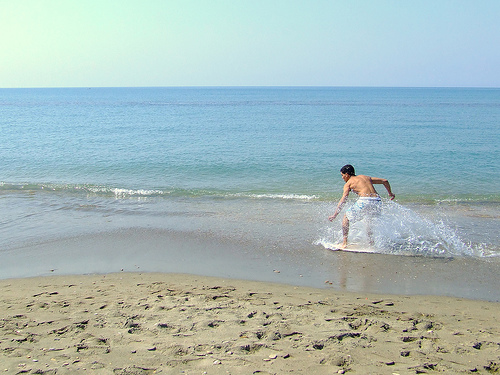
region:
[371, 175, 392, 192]
right arm of young man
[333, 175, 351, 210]
Left arm of young man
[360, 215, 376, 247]
right leg of young man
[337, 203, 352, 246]
Left leg of young man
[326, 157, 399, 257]
Young man of surfboard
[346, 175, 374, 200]
Young man's strong back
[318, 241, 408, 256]
White surfboard in water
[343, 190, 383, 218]
Young man's white swim shorts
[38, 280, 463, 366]
Footprints in the sand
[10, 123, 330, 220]
Blue ocean with small waves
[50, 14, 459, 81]
The sky is blue.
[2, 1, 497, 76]
There are no clouds in the sky.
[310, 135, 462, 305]
There is one boogie boarder.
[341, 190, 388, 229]
His shorts are white.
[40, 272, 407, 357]
Footprints in the sand.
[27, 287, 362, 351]
The sand is tan.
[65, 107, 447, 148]
The ocean is blue.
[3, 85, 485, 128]
No one swimming in the ocean.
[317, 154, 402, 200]
He is a male with brown hair.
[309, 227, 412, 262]
The boogie board is white.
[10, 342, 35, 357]
a footprint in the sand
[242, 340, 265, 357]
a footprint in the sand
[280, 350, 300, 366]
a footprint in the sand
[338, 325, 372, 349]
a footprint in the sand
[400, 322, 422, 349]
a footprint in the sand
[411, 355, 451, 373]
a footprint in the sand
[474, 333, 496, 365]
a footprint in the sand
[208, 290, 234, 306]
a footprint in the sand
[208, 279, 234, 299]
a footprint in the sand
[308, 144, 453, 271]
a person surfing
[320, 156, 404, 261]
Surfer on beach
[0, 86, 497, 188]
Ocean is blue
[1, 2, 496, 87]
Sky is blue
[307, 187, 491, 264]
Splash formed by surfer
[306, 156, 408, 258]
Boy has extended arms on side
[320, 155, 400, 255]
Surfer has black hair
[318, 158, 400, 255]
Surfer has white shorts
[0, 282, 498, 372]
Footprints on sand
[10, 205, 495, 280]
Sand is wet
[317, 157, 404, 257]
Boy bend forward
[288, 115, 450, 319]
man is surfing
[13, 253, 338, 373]
sand is wet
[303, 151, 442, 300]
man's shorts are white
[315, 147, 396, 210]
man's hair is black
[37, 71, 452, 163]
ocean is blue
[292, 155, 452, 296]
man is standing on a surf board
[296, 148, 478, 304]
man is splashing water with surfboard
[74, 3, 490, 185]
sky is blue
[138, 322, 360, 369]
rocks are in the sand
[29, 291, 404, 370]
foot prints are in the sand